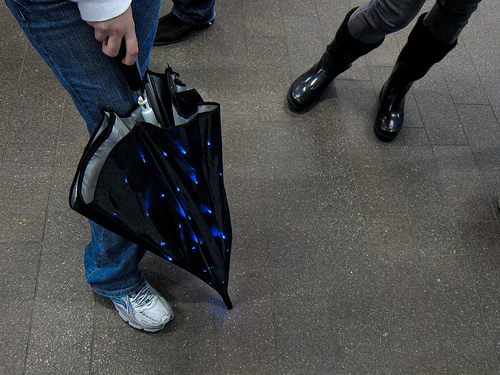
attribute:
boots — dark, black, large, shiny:
[281, 4, 466, 145]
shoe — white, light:
[104, 272, 180, 336]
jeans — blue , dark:
[4, 3, 188, 298]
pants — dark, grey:
[348, 0, 480, 46]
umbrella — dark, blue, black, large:
[59, 37, 276, 310]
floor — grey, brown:
[0, 2, 498, 374]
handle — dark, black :
[106, 37, 151, 96]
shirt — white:
[72, 0, 140, 22]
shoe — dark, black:
[152, 6, 215, 46]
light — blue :
[193, 237, 203, 247]